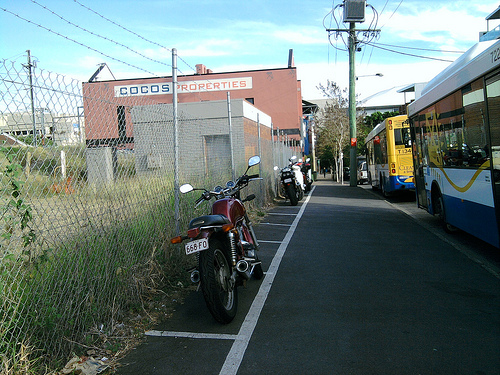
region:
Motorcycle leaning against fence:
[171, 149, 271, 325]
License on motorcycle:
[179, 237, 209, 255]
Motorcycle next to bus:
[177, 152, 264, 331]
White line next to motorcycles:
[204, 175, 324, 373]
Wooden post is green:
[344, 40, 361, 191]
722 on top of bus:
[487, 45, 498, 65]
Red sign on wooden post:
[349, 135, 359, 150]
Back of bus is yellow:
[383, 111, 414, 181]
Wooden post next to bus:
[345, 35, 361, 182]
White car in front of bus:
[355, 160, 368, 184]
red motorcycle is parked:
[149, 125, 287, 339]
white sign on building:
[98, 64, 261, 108]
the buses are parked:
[345, 44, 498, 254]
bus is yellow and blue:
[350, 94, 424, 216]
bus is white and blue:
[384, 51, 497, 241]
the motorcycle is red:
[140, 154, 275, 325]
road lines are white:
[175, 163, 372, 368]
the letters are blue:
[109, 82, 170, 97]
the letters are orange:
[165, 71, 255, 93]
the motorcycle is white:
[270, 159, 320, 202]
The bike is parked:
[128, 169, 315, 324]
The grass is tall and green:
[23, 149, 231, 270]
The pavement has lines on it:
[260, 206, 395, 320]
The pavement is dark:
[352, 235, 422, 372]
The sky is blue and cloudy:
[146, 9, 350, 97]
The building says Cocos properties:
[111, 62, 275, 108]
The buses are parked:
[351, 128, 493, 233]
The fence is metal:
[32, 88, 197, 225]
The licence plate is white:
[171, 232, 218, 262]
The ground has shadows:
[293, 141, 423, 258]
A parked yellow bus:
[354, 120, 418, 212]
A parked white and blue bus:
[383, 26, 497, 249]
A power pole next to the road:
[312, 1, 392, 201]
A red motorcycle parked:
[144, 163, 284, 337]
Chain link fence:
[0, 57, 250, 329]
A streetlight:
[350, 63, 392, 95]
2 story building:
[64, 66, 314, 156]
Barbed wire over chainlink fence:
[3, 0, 207, 102]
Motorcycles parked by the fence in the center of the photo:
[263, 147, 330, 206]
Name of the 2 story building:
[106, 78, 278, 99]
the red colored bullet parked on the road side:
[176, 153, 270, 340]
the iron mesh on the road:
[42, 62, 144, 264]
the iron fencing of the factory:
[104, 11, 179, 91]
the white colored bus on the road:
[408, 62, 497, 209]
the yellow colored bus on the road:
[366, 105, 416, 202]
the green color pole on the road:
[334, 39, 368, 191]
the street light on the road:
[352, 58, 388, 90]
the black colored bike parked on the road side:
[280, 153, 315, 228]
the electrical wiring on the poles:
[360, 20, 438, 63]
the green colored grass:
[57, 248, 129, 324]